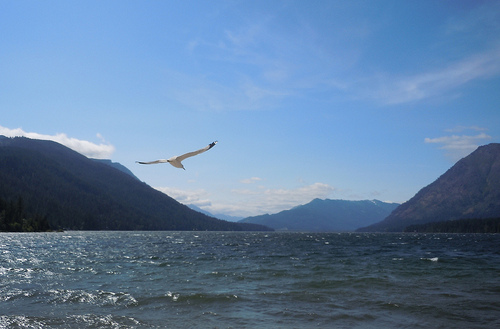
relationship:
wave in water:
[65, 290, 135, 305] [6, 230, 492, 325]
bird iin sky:
[135, 139, 219, 170] [128, 36, 473, 188]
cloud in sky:
[361, 47, 479, 142] [0, 0, 499, 212]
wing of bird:
[176, 140, 219, 161] [135, 139, 219, 170]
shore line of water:
[409, 220, 493, 229] [6, 230, 492, 325]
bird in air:
[135, 139, 219, 170] [287, 24, 471, 133]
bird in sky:
[135, 139, 219, 170] [0, 0, 499, 212]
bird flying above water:
[135, 139, 219, 170] [6, 230, 492, 325]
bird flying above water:
[135, 139, 219, 170] [19, 182, 464, 312]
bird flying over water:
[138, 139, 217, 174] [6, 230, 492, 325]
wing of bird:
[177, 140, 216, 160] [133, 140, 214, 170]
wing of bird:
[137, 158, 167, 164] [133, 140, 214, 170]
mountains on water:
[4, 124, 499, 241] [6, 230, 492, 325]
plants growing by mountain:
[4, 193, 133, 230] [4, 133, 297, 234]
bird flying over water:
[135, 139, 219, 170] [6, 230, 492, 325]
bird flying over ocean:
[135, 139, 219, 170] [5, 235, 498, 327]